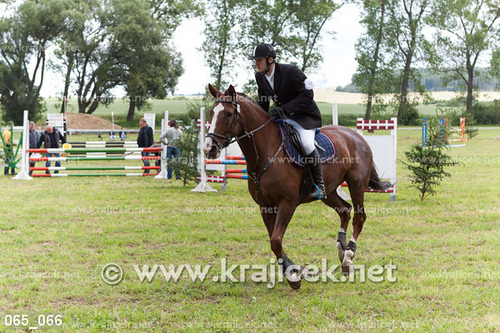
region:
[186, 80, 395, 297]
the horse is brown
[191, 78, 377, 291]
the horse is brown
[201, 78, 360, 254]
the horse is brown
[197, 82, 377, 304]
the horse is brown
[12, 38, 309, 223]
this is a course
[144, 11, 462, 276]
the person is on horseback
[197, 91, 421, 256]
this is a horse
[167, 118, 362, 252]
the horse is brown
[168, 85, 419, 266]
the horse is dark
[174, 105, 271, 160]
the horse is bridled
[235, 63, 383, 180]
the jockey is white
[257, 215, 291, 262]
front legs on the horse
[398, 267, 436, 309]
grass is short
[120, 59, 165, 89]
the bush is green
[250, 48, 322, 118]
a jockey riding the horse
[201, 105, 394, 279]
the horse is brown and white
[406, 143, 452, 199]
a small tree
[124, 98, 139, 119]
a tree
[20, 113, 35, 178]
the pole is white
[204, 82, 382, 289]
Large furry brown horse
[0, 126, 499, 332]
Large open green field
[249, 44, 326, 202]
Small white horse jockey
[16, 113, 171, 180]
Long wooden white fence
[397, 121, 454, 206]
Small green short shrub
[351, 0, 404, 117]
Large tall green tree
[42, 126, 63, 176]
Small short old man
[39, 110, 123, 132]
Large wide brown roof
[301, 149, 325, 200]
Large black long boot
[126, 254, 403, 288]
web address in white print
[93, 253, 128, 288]
copyright symbol in white print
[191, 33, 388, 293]
man riding horse in green field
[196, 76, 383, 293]
brown horse running in grass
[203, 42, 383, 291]
man riding a brown horse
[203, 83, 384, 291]
beautiful brown horse the man is riding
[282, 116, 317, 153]
white pants the rider is wearing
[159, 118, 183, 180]
person wearing blue jeans and a gray sweatshirt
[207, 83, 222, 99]
the horse's right ear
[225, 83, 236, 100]
the horse's left ear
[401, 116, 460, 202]
a small evergreen tree on the right from the horse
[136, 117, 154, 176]
man in a black jacket standing behind the fence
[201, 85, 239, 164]
head of brown and white horse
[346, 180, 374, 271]
hind leg white and brown horse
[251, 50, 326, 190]
a man on horseback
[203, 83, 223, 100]
a letf little ear of a horse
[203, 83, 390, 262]
big brown horse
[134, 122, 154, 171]
man standing in grass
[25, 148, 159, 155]
pole red, white and green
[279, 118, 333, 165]
blue horse saddle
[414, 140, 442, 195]
green bush on the grass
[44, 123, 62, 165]
mand whit coat green on the grass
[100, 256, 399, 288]
watermark on the photo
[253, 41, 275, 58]
helmet the man is wearing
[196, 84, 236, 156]
the horses brown and white face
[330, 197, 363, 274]
horse's hind legs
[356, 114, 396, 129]
red and white checkered fence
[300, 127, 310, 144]
white pants the man is wearing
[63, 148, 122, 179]
four green poles on the fence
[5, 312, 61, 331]
six numbers at the bottom of the photo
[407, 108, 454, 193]
small tree behind the horse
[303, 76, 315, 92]
white patch on the black jacket